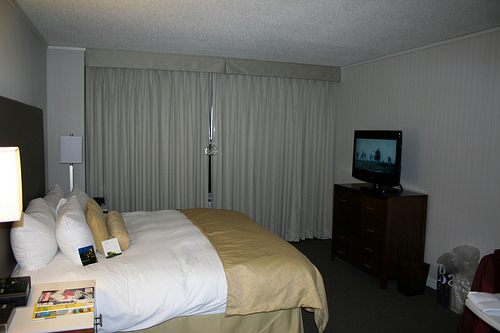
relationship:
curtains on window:
[84, 48, 337, 248] [84, 57, 343, 236]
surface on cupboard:
[20, 292, 97, 331] [4, 276, 110, 330]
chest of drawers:
[333, 182, 426, 291] [336, 194, 382, 272]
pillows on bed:
[10, 187, 126, 272] [17, 206, 319, 333]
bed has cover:
[17, 206, 319, 333] [180, 205, 321, 314]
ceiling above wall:
[20, 6, 499, 66] [338, 32, 499, 281]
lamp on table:
[59, 131, 82, 197] [89, 198, 104, 207]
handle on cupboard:
[95, 310, 104, 332] [0, 279, 98, 333]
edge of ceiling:
[48, 45, 87, 57] [20, 6, 499, 66]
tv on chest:
[354, 131, 400, 183] [333, 182, 426, 291]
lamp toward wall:
[59, 131, 82, 197] [46, 51, 87, 205]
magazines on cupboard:
[34, 286, 96, 315] [0, 279, 98, 333]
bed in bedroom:
[17, 206, 319, 333] [1, 2, 500, 330]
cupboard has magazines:
[0, 279, 98, 333] [34, 286, 96, 315]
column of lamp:
[68, 166, 76, 196] [59, 131, 82, 197]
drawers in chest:
[336, 194, 382, 272] [333, 182, 426, 291]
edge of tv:
[395, 129, 403, 192] [354, 131, 400, 183]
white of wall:
[46, 51, 87, 205] [338, 32, 499, 281]